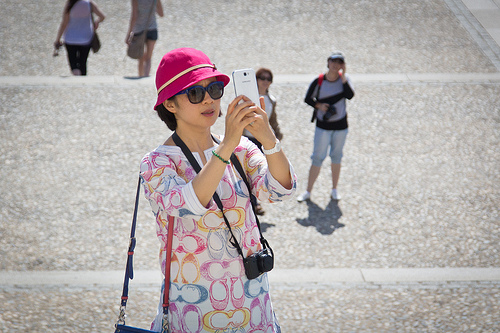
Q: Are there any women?
A: Yes, there is a woman.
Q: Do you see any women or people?
A: Yes, there is a woman.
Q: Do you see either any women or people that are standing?
A: Yes, the woman is standing.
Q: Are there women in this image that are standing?
A: Yes, there is a woman that is standing.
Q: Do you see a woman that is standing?
A: Yes, there is a woman that is standing.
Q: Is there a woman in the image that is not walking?
A: Yes, there is a woman that is standing.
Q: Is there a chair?
A: No, there are no chairs.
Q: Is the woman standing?
A: Yes, the woman is standing.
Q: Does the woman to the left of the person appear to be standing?
A: Yes, the woman is standing.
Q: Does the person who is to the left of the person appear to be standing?
A: Yes, the woman is standing.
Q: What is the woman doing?
A: The woman is standing.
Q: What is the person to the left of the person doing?
A: The woman is standing.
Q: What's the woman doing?
A: The woman is standing.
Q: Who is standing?
A: The woman is standing.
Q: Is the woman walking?
A: No, the woman is standing.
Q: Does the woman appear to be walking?
A: No, the woman is standing.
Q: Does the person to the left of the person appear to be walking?
A: No, the woman is standing.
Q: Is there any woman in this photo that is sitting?
A: No, there is a woman but she is standing.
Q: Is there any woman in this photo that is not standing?
A: No, there is a woman but she is standing.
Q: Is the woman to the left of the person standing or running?
A: The woman is standing.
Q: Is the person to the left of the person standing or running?
A: The woman is standing.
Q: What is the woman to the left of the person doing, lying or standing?
A: The woman is standing.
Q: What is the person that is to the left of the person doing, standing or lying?
A: The woman is standing.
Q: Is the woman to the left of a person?
A: Yes, the woman is to the left of a person.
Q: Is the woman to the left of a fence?
A: No, the woman is to the left of a person.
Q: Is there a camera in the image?
A: Yes, there is a camera.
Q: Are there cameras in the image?
A: Yes, there is a camera.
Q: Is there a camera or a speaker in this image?
A: Yes, there is a camera.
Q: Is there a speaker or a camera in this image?
A: Yes, there is a camera.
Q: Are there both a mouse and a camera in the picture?
A: No, there is a camera but no computer mice.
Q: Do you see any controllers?
A: No, there are no controllers.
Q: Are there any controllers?
A: No, there are no controllers.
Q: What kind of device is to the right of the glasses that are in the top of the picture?
A: The device is a camera.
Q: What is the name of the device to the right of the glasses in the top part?
A: The device is a camera.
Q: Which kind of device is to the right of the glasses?
A: The device is a camera.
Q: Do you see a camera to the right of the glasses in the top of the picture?
A: Yes, there is a camera to the right of the glasses.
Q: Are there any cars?
A: No, there are no cars.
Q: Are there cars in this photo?
A: No, there are no cars.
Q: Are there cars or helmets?
A: No, there are no cars or helmets.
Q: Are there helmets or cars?
A: No, there are no cars or helmets.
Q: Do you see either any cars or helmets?
A: No, there are no cars or helmets.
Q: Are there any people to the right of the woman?
A: Yes, there is a person to the right of the woman.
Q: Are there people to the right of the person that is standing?
A: Yes, there is a person to the right of the woman.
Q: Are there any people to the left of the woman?
A: No, the person is to the right of the woman.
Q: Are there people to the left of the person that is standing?
A: No, the person is to the right of the woman.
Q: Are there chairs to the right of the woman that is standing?
A: No, there is a person to the right of the woman.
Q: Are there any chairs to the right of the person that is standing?
A: No, there is a person to the right of the woman.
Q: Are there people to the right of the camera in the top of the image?
A: Yes, there is a person to the right of the camera.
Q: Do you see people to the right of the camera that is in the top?
A: Yes, there is a person to the right of the camera.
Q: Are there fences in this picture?
A: No, there are no fences.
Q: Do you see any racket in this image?
A: No, there are no rackets.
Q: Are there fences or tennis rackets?
A: No, there are no tennis rackets or fences.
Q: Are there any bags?
A: Yes, there is a bag.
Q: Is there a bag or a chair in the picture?
A: Yes, there is a bag.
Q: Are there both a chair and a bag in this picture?
A: No, there is a bag but no chairs.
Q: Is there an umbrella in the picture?
A: No, there are no umbrellas.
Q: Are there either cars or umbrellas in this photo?
A: No, there are no umbrellas or cars.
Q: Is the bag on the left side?
A: Yes, the bag is on the left of the image.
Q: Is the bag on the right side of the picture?
A: No, the bag is on the left of the image.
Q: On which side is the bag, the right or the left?
A: The bag is on the left of the image.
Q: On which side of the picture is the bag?
A: The bag is on the left of the image.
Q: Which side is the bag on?
A: The bag is on the left of the image.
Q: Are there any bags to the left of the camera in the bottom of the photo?
A: Yes, there is a bag to the left of the camera.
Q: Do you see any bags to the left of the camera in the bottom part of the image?
A: Yes, there is a bag to the left of the camera.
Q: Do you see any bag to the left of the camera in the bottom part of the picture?
A: Yes, there is a bag to the left of the camera.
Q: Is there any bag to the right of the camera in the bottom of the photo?
A: No, the bag is to the left of the camera.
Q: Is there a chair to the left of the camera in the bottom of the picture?
A: No, there is a bag to the left of the camera.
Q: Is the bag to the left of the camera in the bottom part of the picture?
A: Yes, the bag is to the left of the camera.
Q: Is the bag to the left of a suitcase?
A: No, the bag is to the left of the camera.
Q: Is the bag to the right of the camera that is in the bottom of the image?
A: No, the bag is to the left of the camera.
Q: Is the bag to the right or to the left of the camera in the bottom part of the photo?
A: The bag is to the left of the camera.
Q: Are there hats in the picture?
A: Yes, there is a hat.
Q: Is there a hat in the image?
A: Yes, there is a hat.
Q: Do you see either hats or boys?
A: Yes, there is a hat.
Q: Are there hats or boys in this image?
A: Yes, there is a hat.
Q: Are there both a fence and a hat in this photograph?
A: No, there is a hat but no fences.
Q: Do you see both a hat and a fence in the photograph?
A: No, there is a hat but no fences.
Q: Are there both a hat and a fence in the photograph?
A: No, there is a hat but no fences.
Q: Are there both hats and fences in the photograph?
A: No, there is a hat but no fences.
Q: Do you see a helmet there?
A: No, there are no helmets.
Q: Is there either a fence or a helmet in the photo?
A: No, there are no helmets or fences.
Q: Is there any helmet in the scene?
A: No, there are no helmets.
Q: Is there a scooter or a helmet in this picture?
A: No, there are no helmets or scooters.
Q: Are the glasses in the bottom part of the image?
A: No, the glasses are in the top of the image.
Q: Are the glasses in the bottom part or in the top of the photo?
A: The glasses are in the top of the image.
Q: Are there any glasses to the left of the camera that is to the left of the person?
A: Yes, there are glasses to the left of the camera.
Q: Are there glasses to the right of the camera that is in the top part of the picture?
A: No, the glasses are to the left of the camera.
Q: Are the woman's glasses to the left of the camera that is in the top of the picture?
A: Yes, the glasses are to the left of the camera.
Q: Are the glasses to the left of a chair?
A: No, the glasses are to the left of the camera.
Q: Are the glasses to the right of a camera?
A: No, the glasses are to the left of a camera.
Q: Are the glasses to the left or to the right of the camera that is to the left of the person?
A: The glasses are to the left of the camera.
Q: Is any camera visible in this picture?
A: Yes, there is a camera.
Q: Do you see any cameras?
A: Yes, there is a camera.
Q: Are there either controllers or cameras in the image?
A: Yes, there is a camera.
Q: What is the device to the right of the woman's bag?
A: The device is a camera.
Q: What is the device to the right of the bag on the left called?
A: The device is a camera.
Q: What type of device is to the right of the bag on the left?
A: The device is a camera.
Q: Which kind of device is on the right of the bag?
A: The device is a camera.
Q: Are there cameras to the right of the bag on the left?
A: Yes, there is a camera to the right of the bag.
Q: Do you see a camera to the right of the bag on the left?
A: Yes, there is a camera to the right of the bag.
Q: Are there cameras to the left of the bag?
A: No, the camera is to the right of the bag.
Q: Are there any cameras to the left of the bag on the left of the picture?
A: No, the camera is to the right of the bag.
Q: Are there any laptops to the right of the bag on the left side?
A: No, there is a camera to the right of the bag.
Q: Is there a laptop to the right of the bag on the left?
A: No, there is a camera to the right of the bag.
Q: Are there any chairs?
A: No, there are no chairs.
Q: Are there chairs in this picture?
A: No, there are no chairs.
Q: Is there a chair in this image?
A: No, there are no chairs.